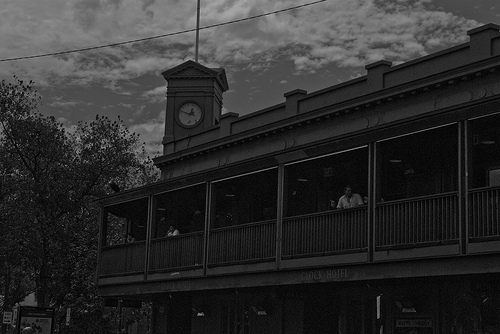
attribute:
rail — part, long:
[97, 238, 149, 254]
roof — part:
[154, 22, 500, 165]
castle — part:
[92, 22, 497, 333]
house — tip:
[93, 22, 497, 333]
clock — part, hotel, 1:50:
[175, 101, 205, 128]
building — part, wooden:
[93, 20, 499, 331]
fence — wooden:
[144, 227, 203, 272]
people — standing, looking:
[327, 185, 387, 209]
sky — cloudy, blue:
[2, 1, 498, 188]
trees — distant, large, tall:
[2, 76, 157, 333]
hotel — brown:
[81, 20, 500, 331]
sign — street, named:
[17, 303, 54, 333]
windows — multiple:
[104, 107, 499, 246]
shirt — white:
[335, 193, 364, 206]